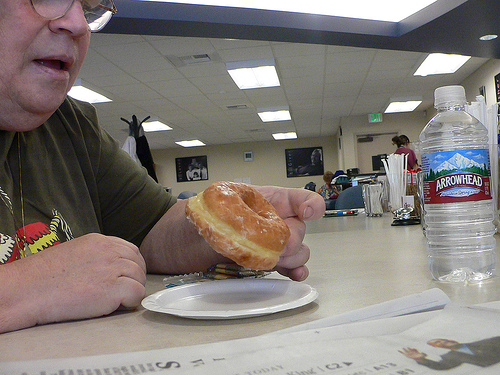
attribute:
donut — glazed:
[183, 174, 294, 275]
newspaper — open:
[5, 268, 487, 373]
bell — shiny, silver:
[382, 201, 424, 248]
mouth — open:
[30, 54, 73, 79]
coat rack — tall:
[112, 107, 156, 147]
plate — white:
[139, 276, 319, 321]